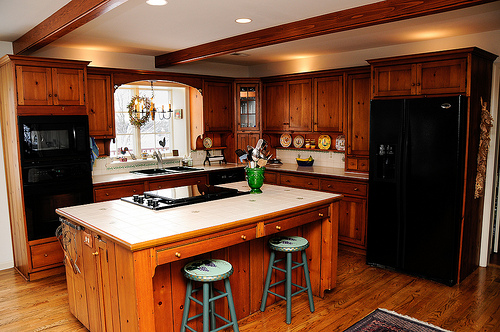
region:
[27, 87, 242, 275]
this is a kitchen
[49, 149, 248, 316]
the kitchen is country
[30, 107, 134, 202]
this is an oven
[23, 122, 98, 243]
the oven is black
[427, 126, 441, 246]
this is a fridge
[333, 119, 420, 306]
the fridge is black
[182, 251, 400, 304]
these are two stools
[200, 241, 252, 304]
the stools are green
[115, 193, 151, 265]
this is a countertop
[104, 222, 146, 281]
the countertop is white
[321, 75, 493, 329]
a black refrigerator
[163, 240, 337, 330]
two blue bar stools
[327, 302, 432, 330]
a carpet in the kitchen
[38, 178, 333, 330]
a brown wooden island in a kitchen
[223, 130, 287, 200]
a green vase with cooking utensils in it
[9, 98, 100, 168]
a black microwave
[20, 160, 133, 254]
a black oven in a kitchen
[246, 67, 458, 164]
brown wooden cupboards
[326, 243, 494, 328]
brown wooden floor in a kitchen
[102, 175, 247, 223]
black glass stove top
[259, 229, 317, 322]
blue bar stool with flowers on seat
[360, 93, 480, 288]
black side by side refrigerator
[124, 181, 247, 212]
black cooktop in island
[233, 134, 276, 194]
green container full of utensils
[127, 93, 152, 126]
floral wreath hanging in window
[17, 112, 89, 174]
black microwave under cabinet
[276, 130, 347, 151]
four plates on a shelf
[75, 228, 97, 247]
electrical outlet in island wall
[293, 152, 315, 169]
basket of bananas on counter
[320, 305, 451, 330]
blue area rug on floor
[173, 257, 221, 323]
GREEN STOOL IN KITCHEN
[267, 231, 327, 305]
GREEN STOOL IN KITCHEN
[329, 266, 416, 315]
WOOD FLOOR OF KITCHEN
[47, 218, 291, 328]
WOOD CABINETS OF KITCHEN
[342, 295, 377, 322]
ORNATE RUG ON FLOOR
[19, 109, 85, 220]
BLACK OVEN IN CABINETS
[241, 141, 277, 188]
GREEN VASE ON COUNTER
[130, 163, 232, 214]
BLACK STONE ON COUNTER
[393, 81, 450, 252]
BLACK FRIDGE ON RIGHT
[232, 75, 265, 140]
SMALL WINDOW IN KITCHEN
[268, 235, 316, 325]
blue stools at counter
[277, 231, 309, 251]
top of stool design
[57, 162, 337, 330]
island in middle of kitchen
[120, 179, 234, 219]
stove on top of island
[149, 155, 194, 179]
sink in corner of kitchen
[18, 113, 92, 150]
microwave in kitchen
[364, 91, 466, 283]
large built in fridge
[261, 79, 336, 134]
brown cabinets in kitch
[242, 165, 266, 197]
green vase on island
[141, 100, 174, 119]
small candle holder hanging down